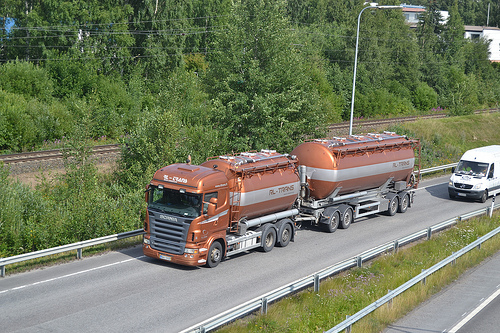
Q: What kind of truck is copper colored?
A: A semi truck.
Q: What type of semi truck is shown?
A: A tanker truck.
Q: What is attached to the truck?
A: Two rigs.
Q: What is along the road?
A: Trees.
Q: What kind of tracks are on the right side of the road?
A: Railroad.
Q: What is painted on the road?
A: White lines.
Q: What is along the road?
A: Guard rails.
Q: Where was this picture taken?
A: On the highway.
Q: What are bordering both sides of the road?
A: Guardrails.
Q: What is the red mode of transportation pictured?
A: A tanker.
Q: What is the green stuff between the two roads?
A: Grass.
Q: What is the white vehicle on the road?
A: A van.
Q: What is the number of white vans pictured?
A: One.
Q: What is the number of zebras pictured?
A: Zero.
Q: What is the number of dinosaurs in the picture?
A: Zero.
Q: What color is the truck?
A: Brown.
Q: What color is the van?
A: White.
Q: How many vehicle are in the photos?
A: 2.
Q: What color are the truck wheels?
A: Black.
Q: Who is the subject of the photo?
A: The brown truck.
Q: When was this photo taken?
A: During the day.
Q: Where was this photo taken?
A: Overpass.